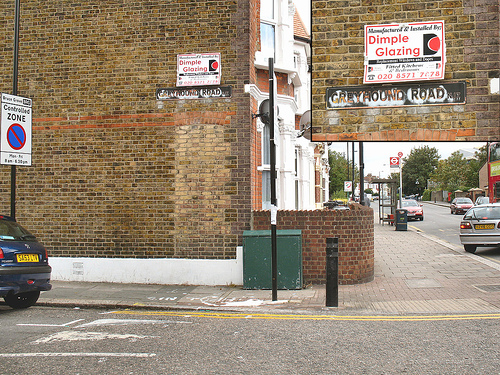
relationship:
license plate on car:
[16, 252, 41, 261] [0, 215, 52, 310]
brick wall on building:
[248, 207, 377, 289] [1, 1, 326, 286]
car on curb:
[449, 205, 498, 263] [48, 295, 325, 325]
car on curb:
[394, 190, 424, 229] [48, 295, 325, 325]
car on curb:
[0, 217, 52, 315] [48, 295, 325, 325]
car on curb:
[447, 195, 473, 219] [48, 295, 325, 325]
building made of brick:
[1, 1, 326, 286] [188, 25, 223, 40]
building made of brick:
[1, 1, 326, 286] [196, 206, 213, 214]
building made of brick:
[1, 1, 326, 286] [103, 82, 130, 92]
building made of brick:
[1, 1, 326, 286] [76, 155, 95, 162]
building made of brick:
[1, 1, 326, 286] [153, 170, 175, 178]